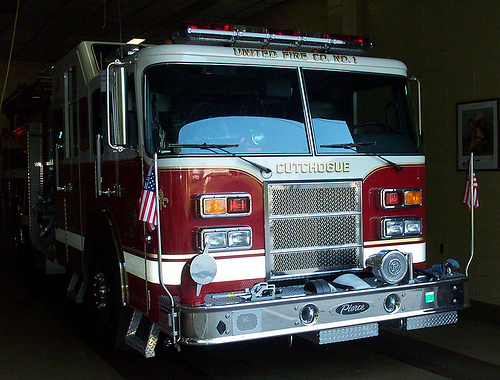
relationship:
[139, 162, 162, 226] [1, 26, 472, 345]
flag on truck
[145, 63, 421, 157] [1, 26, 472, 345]
window on truck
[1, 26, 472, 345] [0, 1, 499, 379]
truck in garage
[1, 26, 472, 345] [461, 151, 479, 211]
truck with flag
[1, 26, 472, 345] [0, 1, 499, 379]
truck parked in garage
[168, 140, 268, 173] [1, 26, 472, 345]
wiper on truck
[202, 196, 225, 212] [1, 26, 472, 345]
signal light on truck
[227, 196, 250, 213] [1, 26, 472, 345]
light on truck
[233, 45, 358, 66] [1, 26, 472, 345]
name on truck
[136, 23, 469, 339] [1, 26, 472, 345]
front of truck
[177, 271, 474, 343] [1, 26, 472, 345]
bumper on truck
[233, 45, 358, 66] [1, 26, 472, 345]
name that built truck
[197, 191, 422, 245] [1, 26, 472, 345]
headlights of truck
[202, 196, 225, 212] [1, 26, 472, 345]
signal light of truck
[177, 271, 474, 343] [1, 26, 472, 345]
bumper of truck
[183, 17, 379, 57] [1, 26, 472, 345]
flashing lights for truck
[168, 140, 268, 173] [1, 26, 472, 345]
wiper for truck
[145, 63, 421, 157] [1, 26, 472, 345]
window for truck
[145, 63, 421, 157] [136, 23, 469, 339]
window on front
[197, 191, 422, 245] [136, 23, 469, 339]
headlights on front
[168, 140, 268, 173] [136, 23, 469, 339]
wiper on front